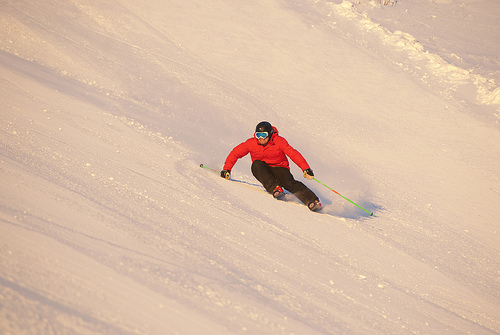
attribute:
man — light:
[223, 119, 323, 216]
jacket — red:
[223, 125, 311, 169]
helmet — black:
[254, 121, 273, 138]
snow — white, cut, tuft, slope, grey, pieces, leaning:
[1, 1, 498, 334]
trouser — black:
[251, 158, 320, 205]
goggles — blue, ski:
[254, 128, 272, 143]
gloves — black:
[216, 166, 318, 181]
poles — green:
[195, 162, 381, 219]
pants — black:
[250, 156, 321, 205]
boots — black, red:
[269, 184, 326, 216]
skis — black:
[270, 189, 326, 216]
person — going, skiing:
[218, 119, 322, 215]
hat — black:
[254, 122, 272, 135]